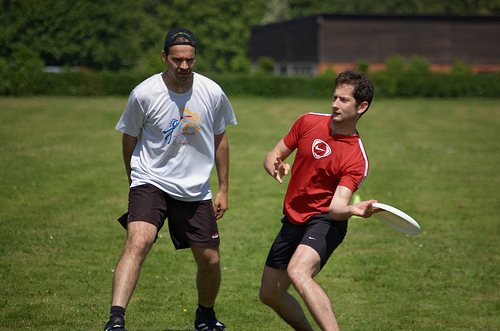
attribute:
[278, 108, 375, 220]
shirt — red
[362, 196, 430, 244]
disc — white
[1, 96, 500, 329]
grass — green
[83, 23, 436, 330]
people — playing, white, dressed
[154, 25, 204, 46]
hat — black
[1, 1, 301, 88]
trees — green